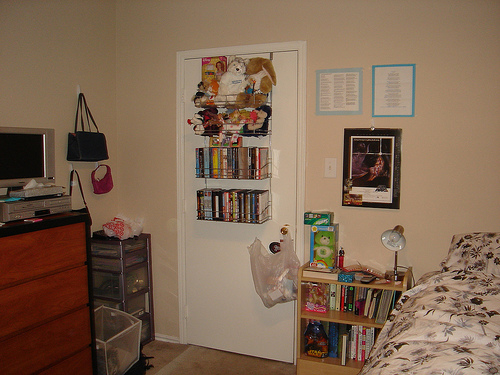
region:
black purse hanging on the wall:
[60, 86, 116, 170]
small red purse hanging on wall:
[89, 162, 118, 195]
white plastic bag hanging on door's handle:
[246, 228, 304, 325]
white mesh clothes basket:
[90, 302, 152, 370]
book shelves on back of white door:
[187, 142, 282, 233]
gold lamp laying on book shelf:
[379, 218, 411, 287]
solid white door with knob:
[165, 30, 317, 371]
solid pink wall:
[103, 15, 172, 134]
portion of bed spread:
[442, 231, 498, 373]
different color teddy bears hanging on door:
[175, 52, 287, 111]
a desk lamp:
[371, 216, 408, 288]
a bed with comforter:
[355, 224, 498, 371]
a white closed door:
[167, 42, 308, 365]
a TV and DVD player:
[0, 123, 77, 228]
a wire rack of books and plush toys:
[184, 55, 278, 228]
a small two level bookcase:
[289, 256, 415, 373]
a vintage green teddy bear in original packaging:
[300, 217, 342, 282]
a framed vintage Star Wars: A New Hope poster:
[337, 123, 402, 213]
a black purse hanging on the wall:
[58, 82, 113, 163]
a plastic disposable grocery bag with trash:
[237, 226, 302, 310]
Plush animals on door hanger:
[185, 51, 277, 146]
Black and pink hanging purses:
[60, 80, 123, 240]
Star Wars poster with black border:
[337, 120, 404, 215]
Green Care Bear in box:
[305, 220, 344, 273]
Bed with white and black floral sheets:
[350, 220, 497, 372]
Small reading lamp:
[372, 222, 417, 291]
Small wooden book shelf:
[283, 253, 412, 373]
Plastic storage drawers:
[81, 222, 169, 366]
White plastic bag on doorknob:
[240, 223, 305, 314]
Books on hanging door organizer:
[185, 140, 275, 237]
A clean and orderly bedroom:
[15, 9, 482, 362]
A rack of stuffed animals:
[188, 54, 278, 136]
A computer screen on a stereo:
[5, 111, 73, 226]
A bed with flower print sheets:
[408, 223, 493, 365]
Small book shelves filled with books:
[291, 264, 406, 367]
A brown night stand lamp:
[370, 219, 415, 292]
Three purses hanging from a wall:
[56, 74, 116, 233]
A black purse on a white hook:
[61, 70, 109, 164]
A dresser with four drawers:
[12, 210, 107, 372]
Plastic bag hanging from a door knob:
[238, 228, 302, 314]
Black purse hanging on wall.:
[61, 85, 114, 164]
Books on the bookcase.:
[294, 258, 409, 374]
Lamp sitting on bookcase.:
[375, 223, 419, 295]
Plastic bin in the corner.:
[90, 221, 160, 344]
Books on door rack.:
[190, 146, 275, 228]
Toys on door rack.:
[189, 50, 277, 137]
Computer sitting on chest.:
[1, 126, 60, 193]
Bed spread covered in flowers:
[392, 227, 499, 370]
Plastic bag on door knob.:
[247, 226, 305, 312]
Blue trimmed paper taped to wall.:
[312, 63, 431, 124]